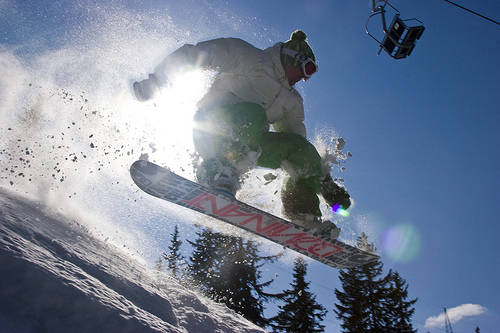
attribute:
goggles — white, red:
[281, 48, 318, 83]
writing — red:
[180, 192, 344, 261]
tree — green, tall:
[332, 232, 421, 332]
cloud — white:
[420, 302, 491, 332]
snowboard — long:
[129, 157, 380, 270]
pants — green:
[190, 101, 325, 215]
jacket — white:
[154, 36, 307, 140]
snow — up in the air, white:
[2, 2, 348, 256]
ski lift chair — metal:
[363, 3, 424, 60]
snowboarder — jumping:
[129, 29, 356, 243]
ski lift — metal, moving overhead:
[365, 2, 427, 63]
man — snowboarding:
[129, 27, 354, 242]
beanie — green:
[280, 29, 317, 68]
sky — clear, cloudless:
[2, 2, 499, 333]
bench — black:
[380, 19, 424, 60]